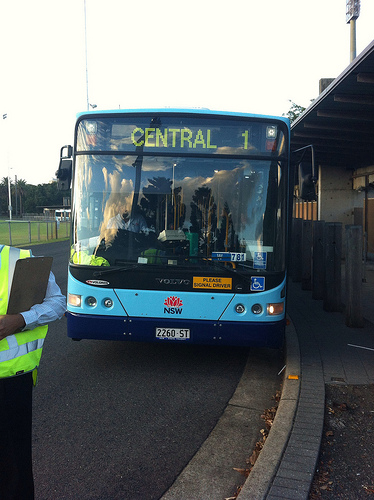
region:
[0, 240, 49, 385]
man wearing bright green vest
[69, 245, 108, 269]
bright green vest on dash of bus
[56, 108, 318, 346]
bus is blue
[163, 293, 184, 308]
bus has red flower on front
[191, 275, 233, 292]
yellow sign on front of bus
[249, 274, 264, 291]
blue handicapped sign on front of bus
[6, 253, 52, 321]
man holding brown clipbaord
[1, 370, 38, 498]
man wearing black pants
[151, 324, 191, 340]
white license plate on front of bus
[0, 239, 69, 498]
man standing in front of bus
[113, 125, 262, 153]
The marquee of the bus that displays Central with the a number.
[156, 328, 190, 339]
License plate in front of bus.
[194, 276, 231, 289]
Orange sticker with black writing on front of bus.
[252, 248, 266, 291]
Two blue handicap stickers on bus window.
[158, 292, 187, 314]
Black letters with red flower design on front of bus.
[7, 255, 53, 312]
Brown clipboard in person's arm.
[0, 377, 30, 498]
Black pants worn by person holding the clipboard.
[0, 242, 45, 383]
Safety vest held by person holding the clipboard.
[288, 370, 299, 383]
Orange reflector on sidewalk's curb.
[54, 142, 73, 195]
Left side view mirror on bus.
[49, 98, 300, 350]
the front of a city bus parked on a curb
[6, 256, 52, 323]
the back of a brown clipboard a man is holding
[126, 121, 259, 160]
the yellow digital sign on the bus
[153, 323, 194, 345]
the white and black license plate on the bus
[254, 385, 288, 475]
brown leaves in the gutter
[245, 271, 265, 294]
a handicap placard on the front of the bus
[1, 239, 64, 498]
a man wearing a bright yellow safety vest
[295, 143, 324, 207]
a large black side rear view mirror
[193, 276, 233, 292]
a yellow sign on the front of the bus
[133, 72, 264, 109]
a very white cloudy sky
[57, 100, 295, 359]
a volvo bus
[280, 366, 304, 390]
orange reflector on curb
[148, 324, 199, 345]
license plate on front of bus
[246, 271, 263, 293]
sign stating wheelchair accesible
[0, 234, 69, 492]
man holding clip board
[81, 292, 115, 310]
head lights of bus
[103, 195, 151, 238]
person driving the bus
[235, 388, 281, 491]
leaves and trash in gutter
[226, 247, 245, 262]
bus number 781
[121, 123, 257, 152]
sign that says bus route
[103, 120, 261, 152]
The Route Number of this Bus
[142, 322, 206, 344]
The license plate of this bus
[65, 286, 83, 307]
One of the two bus front lights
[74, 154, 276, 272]
The front window of this bus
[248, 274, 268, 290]
This sign shows the bus is equipped for the disabled.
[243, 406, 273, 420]
Dried leaves on the curbside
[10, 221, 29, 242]
A green play field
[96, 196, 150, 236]
A rider of this bus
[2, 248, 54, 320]
Aa writing clip board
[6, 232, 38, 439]
A person with a traffic vest